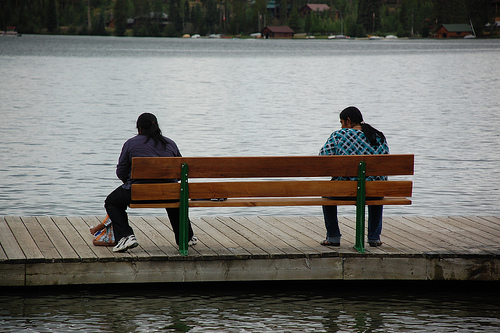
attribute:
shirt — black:
[116, 131, 187, 188]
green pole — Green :
[175, 165, 192, 255]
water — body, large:
[202, 292, 242, 332]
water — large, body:
[2, 30, 497, 221]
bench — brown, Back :
[116, 140, 448, 223]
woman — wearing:
[320, 106, 390, 248]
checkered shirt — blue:
[316, 128, 389, 181]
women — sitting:
[71, 95, 426, 255]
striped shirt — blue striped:
[316, 125, 391, 181]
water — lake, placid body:
[0, 37, 499, 329]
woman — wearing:
[103, 113, 198, 253]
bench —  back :
[126, 150, 421, 250]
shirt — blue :
[115, 134, 182, 189]